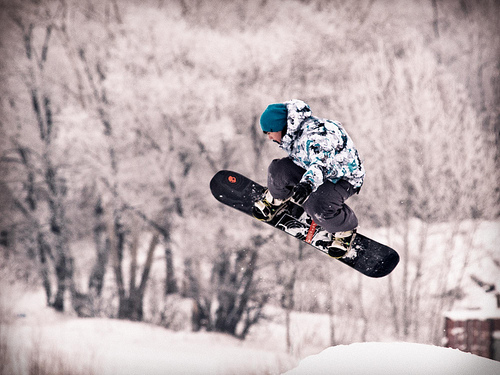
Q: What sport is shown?
A: Snowboarding.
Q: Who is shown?
A: Snowboarder.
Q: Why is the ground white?
A: Snow.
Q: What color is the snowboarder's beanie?
A: Blue.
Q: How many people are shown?
A: One.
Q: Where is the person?
A: Air.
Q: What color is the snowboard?
A: Black.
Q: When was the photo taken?
A: Winter.